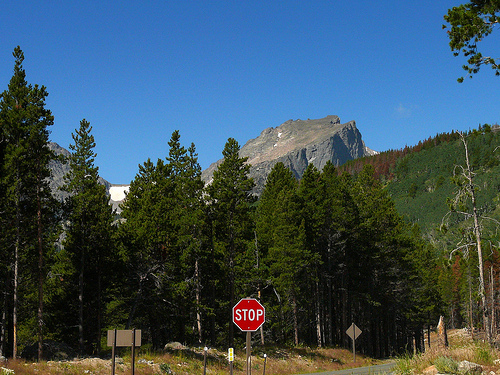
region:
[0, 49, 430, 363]
a bunch of green tall pines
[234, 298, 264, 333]
red stop signboard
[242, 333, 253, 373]
thin gray pole of signboard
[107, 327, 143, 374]
wooden rectangle signboard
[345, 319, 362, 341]
rhombus signboard in pole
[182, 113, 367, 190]
big mountain behind pines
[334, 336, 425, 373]
pavement path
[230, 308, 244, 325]
S white letter on red signboard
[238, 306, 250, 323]
T white letter on red signboard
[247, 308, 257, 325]
O white letter on red signboard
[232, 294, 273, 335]
red and white stop sign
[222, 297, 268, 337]
white and red stop sign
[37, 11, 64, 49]
white clouds in blue sky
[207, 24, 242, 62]
white clouds in blue sky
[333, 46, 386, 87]
white clouds in blue sky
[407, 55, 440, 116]
white clouds in blue sky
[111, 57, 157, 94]
white clouds in blue sky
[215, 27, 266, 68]
white clouds in blue sky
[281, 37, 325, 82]
white clouds in blue sky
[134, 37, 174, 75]
white clouds in blue sky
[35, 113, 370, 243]
A large mountain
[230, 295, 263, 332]
a stop sign on a wooden post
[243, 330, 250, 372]
a wooden pole in the ground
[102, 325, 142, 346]
the back of a metal sign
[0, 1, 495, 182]
a clear, blue sky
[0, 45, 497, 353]
a large forested area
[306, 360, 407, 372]
an asphalt road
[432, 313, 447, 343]
a tree stump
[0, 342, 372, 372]
a grassy hill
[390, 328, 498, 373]
a grassy hill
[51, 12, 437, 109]
a clear blue sky overhead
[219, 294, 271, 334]
a red and white sign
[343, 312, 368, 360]
a triangular traffic sign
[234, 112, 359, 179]
a tall mountain of granite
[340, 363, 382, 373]
a lonely paved road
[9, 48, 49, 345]
a tall evergreen tree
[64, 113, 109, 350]
a tall evergreen tree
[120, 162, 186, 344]
a tall evergreen tree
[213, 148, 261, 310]
a tall evergreen tree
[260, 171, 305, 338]
a tall evergreen tree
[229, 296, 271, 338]
stop sign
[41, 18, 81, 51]
blue sky with no clouds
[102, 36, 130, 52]
blue sky with no clouds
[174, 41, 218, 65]
blue sky with no clouds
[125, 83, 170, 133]
blue sky with no clouds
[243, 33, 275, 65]
blue sky with no clouds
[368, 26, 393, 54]
blue sky with no clouds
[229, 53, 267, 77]
blue sky with no clouds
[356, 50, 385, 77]
blue sky with no clouds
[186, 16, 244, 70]
blue sky with no clouds